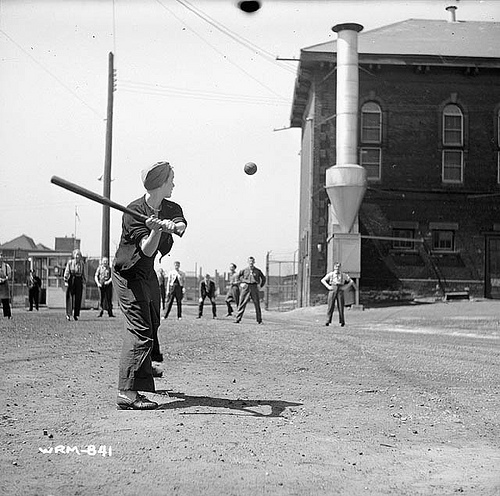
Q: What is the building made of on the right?
A: Brick.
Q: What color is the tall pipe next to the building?
A: White.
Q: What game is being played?
A: Baseball.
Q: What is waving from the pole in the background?
A: Flag.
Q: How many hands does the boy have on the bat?
A: Two.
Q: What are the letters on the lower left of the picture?
A: WRM.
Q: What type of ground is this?
A: Gravel.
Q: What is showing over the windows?
A: Arches.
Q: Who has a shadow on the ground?
A: Person with baseball bat.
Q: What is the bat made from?
A: Wood.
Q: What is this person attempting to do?
A: Hit the baseball.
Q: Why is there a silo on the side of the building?
A: On a farm.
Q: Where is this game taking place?
A: In a schoolyard.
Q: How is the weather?
A: It's sunny.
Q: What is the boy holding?
A: A baseball bat.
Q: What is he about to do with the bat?
A: Hit a ball.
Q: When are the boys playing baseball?
A: At recess.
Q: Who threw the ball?
A: A boy far away.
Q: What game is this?
A: Baseball.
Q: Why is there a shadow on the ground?
A: It's sunny.